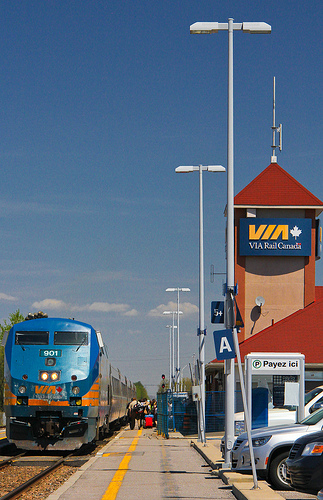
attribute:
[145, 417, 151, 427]
suit case — red 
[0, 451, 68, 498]
track — metal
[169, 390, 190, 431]
phone booth — blue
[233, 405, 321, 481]
car — Silver 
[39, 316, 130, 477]
train — large 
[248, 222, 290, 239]
via — Large , orange 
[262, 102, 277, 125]
ground — silver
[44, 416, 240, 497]
platform — Concrete 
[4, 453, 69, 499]
tracks — Metal 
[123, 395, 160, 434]
people — standing 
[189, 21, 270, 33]
headlights — illuminated 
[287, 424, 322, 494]
vehicle — black 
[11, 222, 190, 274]
sky — blue 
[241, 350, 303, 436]
phone booth — silver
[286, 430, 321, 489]
vehicle — black 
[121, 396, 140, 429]
policeman — dark 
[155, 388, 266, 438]
fence — blue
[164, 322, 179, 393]
pole — tall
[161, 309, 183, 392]
pole — tall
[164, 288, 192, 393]
pole — tall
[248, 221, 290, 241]
via — yellow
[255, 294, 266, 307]
dish — small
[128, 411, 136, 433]
pants — black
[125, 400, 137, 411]
shirt — tan